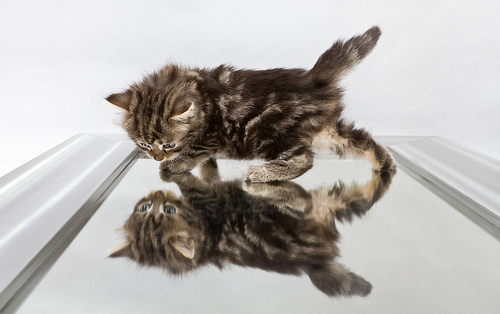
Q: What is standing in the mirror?
A: The cat.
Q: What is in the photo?
A: A kitten.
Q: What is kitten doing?
A: Looking at reflection.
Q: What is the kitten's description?
A: Black and grey.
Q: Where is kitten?
A: On a glass or mirror.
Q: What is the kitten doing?
A: Walking on mirror.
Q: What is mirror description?
A: Long with white trim.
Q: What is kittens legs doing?
A: Walking.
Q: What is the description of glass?
A: Smooth.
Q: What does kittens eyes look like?
A: Dark.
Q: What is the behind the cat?
A: Wall.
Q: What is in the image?
A: Grey cat.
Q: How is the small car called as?
A: Kitten.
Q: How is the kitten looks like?
A: Stripes.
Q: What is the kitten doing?
A: Looking in a mirror.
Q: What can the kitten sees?
A: Reflection.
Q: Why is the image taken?
A: Remembrance.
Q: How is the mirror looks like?
A: White frame.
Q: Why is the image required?
A: Remembrance.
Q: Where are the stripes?
A: On kitten.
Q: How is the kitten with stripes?
A: Small.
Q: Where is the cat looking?
A: At reflection.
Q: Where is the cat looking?
A: Down.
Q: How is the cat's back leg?
A: Stretched out.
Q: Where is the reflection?
A: Under cat.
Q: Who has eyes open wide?
A: Kitten.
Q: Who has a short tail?
A: Kitten.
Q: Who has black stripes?
A: Kitten.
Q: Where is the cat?
A: On a mirror.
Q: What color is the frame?
A: White.